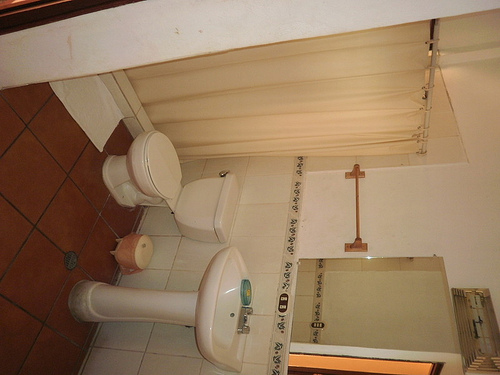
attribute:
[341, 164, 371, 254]
rack — wooden 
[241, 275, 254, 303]
item — blue 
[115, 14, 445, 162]
shower curtain — white 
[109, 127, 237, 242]
toilet — white 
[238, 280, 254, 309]
sopdish — blue 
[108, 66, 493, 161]
wall — white 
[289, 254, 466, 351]
mirror — rectangular 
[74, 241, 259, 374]
sink — white 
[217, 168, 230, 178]
handle — silver 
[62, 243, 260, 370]
sink — white 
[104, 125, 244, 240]
toilet — white , ceramic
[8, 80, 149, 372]
tiled floor — red 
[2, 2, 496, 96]
wall — white 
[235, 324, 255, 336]
handle — silver 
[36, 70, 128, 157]
towel — white 